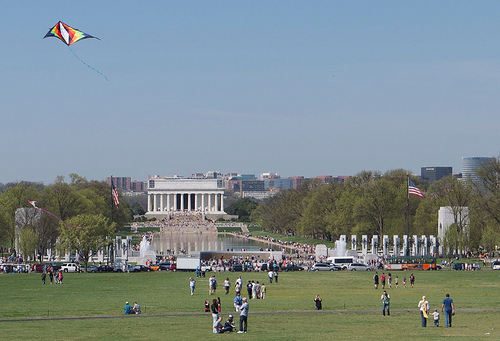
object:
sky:
[0, 1, 498, 192]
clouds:
[208, 25, 309, 108]